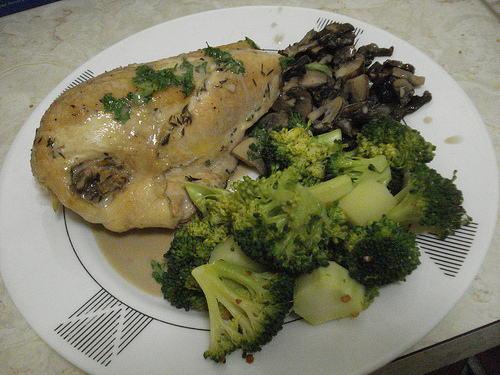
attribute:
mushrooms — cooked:
[267, 21, 437, 146]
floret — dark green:
[343, 212, 425, 290]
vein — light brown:
[42, 4, 75, 59]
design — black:
[417, 210, 485, 281]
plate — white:
[19, 22, 467, 371]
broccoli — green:
[229, 175, 351, 277]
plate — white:
[1, 5, 498, 373]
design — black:
[52, 288, 152, 366]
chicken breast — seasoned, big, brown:
[30, 37, 284, 233]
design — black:
[54, 69, 95, 101]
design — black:
[317, 16, 366, 48]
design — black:
[415, 221, 479, 277]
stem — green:
[193, 258, 247, 320]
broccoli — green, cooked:
[153, 115, 464, 361]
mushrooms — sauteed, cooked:
[230, 19, 433, 178]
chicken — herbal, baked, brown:
[31, 35, 284, 250]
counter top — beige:
[428, 14, 475, 59]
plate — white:
[25, 239, 104, 340]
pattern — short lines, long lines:
[50, 294, 154, 366]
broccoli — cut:
[165, 153, 454, 344]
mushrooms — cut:
[283, 25, 398, 125]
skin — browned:
[52, 103, 89, 157]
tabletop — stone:
[9, 20, 61, 60]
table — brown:
[463, 32, 495, 82]